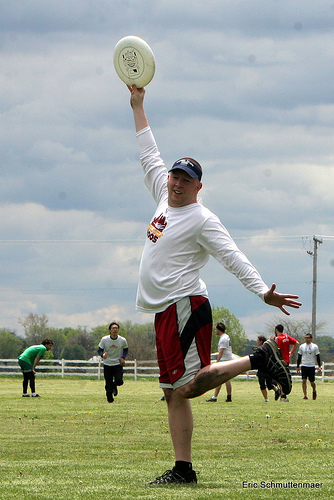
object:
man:
[17, 338, 53, 400]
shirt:
[18, 344, 48, 367]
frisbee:
[113, 36, 156, 89]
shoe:
[148, 470, 198, 488]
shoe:
[252, 337, 294, 397]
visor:
[168, 157, 202, 179]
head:
[166, 157, 203, 206]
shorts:
[170, 301, 213, 390]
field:
[0, 380, 332, 499]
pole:
[307, 234, 322, 347]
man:
[97, 322, 128, 401]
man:
[124, 83, 302, 485]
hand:
[263, 283, 303, 317]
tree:
[23, 312, 50, 348]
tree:
[213, 305, 246, 354]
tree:
[262, 319, 321, 363]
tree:
[0, 327, 21, 359]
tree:
[59, 343, 87, 371]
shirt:
[98, 336, 130, 369]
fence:
[2, 359, 334, 384]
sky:
[0, 1, 333, 318]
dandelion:
[265, 414, 270, 421]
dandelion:
[305, 423, 310, 430]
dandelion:
[316, 438, 322, 445]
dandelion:
[88, 410, 93, 416]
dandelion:
[292, 445, 298, 450]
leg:
[166, 386, 194, 463]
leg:
[175, 355, 252, 400]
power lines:
[1, 233, 333, 249]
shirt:
[98, 349, 127, 359]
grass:
[1, 374, 334, 383]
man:
[295, 333, 324, 401]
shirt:
[297, 343, 321, 369]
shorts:
[308, 367, 315, 381]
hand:
[126, 83, 147, 110]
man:
[274, 325, 297, 364]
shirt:
[275, 335, 298, 364]